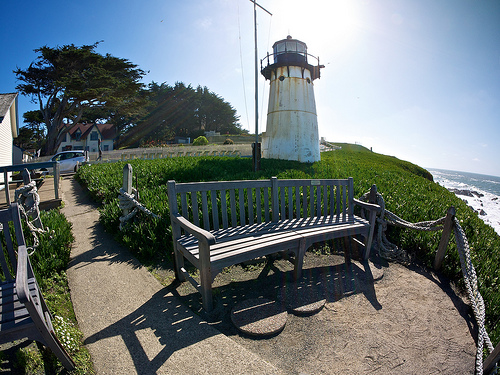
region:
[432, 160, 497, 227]
part of the ocean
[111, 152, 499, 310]
green grass on ground sloping down towards the water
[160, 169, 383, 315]
a large bench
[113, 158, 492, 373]
heavy rope and wooden posts forming a barrier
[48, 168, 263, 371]
walkway next to grass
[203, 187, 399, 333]
stepping stones beneath bench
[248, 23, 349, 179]
old lighthouse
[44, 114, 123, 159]
large white house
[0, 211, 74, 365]
small flowers growing beneath bench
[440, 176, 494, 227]
rocks on the shore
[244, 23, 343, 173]
old rusty white lighthouse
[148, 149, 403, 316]
weathered wooden park bench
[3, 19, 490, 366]
park bench near lighthouse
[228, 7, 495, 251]
lighthouse near the ocean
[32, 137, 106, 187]
small silver compact car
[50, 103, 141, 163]
small white house with red roof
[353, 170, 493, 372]
fence made from boat rope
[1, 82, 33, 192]
white building with black shingles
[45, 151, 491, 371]
wooden bench on concrete pad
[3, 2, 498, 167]
The sky is blue.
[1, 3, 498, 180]
The sky is clear.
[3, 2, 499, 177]
The sky is cloudless.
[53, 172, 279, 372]
The sidewalk is paved.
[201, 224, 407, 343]
The paving stones are round.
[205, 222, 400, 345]
Paving stones in front of a bench.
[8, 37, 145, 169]
The tree is green.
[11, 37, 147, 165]
The tree is leaning.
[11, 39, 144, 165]
The tree is leafy.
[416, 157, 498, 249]
The water is blue.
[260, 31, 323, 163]
A lighthouse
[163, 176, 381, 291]
A wood bench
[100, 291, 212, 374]
Bench shadow on sidewalk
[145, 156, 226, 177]
Dark green long grass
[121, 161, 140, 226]
white wood post with a rope wrapped around it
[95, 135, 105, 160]
A walking person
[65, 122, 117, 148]
A multistory house with a brown roof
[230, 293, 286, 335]
Round cement step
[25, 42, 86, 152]
Large slightly leaning tree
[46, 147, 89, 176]
Small grey parked vehicle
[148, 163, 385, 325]
The bench is wood.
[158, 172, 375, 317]
The bench is unpainted.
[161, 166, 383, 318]
The bench is vacant.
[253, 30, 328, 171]
The lighthouse is tall.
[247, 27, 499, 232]
The lighthouse overlooks the water.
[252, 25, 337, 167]
The lighthouse is white.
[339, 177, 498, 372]
The fence is wood and rope.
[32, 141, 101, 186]
The car is silver.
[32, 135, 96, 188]
The car is parked.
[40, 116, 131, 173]
The house is white.